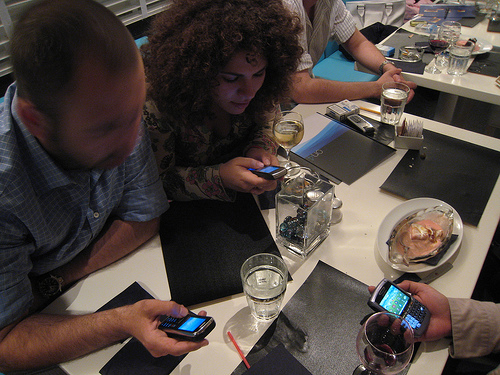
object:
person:
[364, 278, 500, 375]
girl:
[137, 0, 308, 206]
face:
[206, 44, 267, 116]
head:
[139, 0, 306, 127]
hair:
[130, 0, 306, 128]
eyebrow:
[254, 63, 268, 74]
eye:
[220, 75, 238, 83]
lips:
[229, 102, 250, 109]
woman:
[136, 0, 304, 205]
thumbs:
[231, 156, 265, 171]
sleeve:
[0, 205, 39, 329]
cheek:
[211, 79, 238, 105]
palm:
[364, 278, 450, 341]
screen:
[376, 281, 410, 319]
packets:
[325, 98, 360, 124]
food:
[392, 218, 445, 260]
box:
[394, 124, 425, 152]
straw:
[225, 328, 251, 369]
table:
[0, 99, 500, 375]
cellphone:
[343, 112, 376, 135]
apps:
[391, 304, 397, 310]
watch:
[377, 59, 395, 76]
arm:
[445, 296, 500, 359]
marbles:
[277, 222, 289, 234]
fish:
[384, 202, 456, 267]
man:
[0, 0, 210, 375]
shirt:
[445, 298, 500, 375]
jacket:
[140, 63, 283, 203]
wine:
[271, 119, 304, 153]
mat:
[230, 259, 419, 375]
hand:
[217, 156, 280, 196]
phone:
[365, 277, 430, 339]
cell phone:
[153, 312, 217, 343]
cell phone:
[246, 165, 288, 181]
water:
[378, 87, 408, 126]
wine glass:
[272, 109, 305, 177]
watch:
[35, 271, 65, 302]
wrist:
[104, 304, 129, 349]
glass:
[239, 252, 287, 322]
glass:
[354, 309, 417, 375]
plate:
[373, 197, 463, 272]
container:
[274, 165, 334, 259]